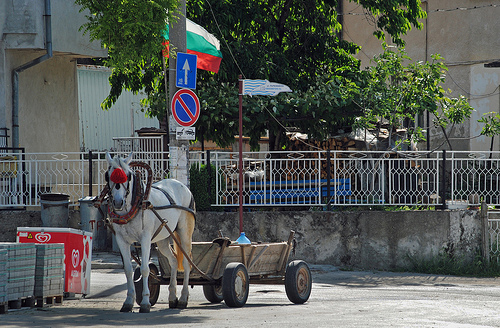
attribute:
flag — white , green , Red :
[155, 17, 222, 77]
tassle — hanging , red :
[110, 166, 128, 183]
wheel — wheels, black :
[284, 257, 312, 303]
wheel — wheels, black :
[223, 261, 250, 307]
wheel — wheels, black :
[205, 283, 223, 303]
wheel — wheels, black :
[134, 267, 161, 304]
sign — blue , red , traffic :
[171, 87, 200, 127]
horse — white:
[69, 143, 258, 313]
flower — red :
[108, 167, 128, 182]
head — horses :
[104, 147, 133, 209]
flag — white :
[235, 73, 292, 97]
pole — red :
[235, 78, 245, 234]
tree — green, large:
[67, 0, 427, 211]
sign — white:
[169, 87, 203, 126]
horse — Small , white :
[95, 146, 197, 314]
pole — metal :
[166, 0, 193, 184]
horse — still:
[102, 158, 199, 308]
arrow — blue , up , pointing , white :
[179, 59, 196, 86]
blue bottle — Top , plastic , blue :
[235, 229, 252, 247]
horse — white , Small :
[106, 150, 197, 312]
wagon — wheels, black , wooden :
[131, 238, 312, 307]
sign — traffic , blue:
[175, 49, 198, 93]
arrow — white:
[181, 56, 190, 84]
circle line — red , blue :
[168, 89, 205, 130]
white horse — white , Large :
[99, 147, 199, 317]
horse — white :
[84, 149, 215, 316]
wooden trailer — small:
[145, 237, 312, 302]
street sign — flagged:
[236, 75, 294, 231]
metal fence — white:
[4, 151, 498, 205]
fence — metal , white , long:
[0, 149, 499, 214]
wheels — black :
[224, 262, 255, 309]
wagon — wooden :
[203, 244, 327, 296]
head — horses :
[89, 149, 139, 221]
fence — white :
[219, 149, 466, 215]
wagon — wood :
[182, 238, 323, 301]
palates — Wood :
[183, 236, 327, 303]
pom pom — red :
[104, 153, 130, 186]